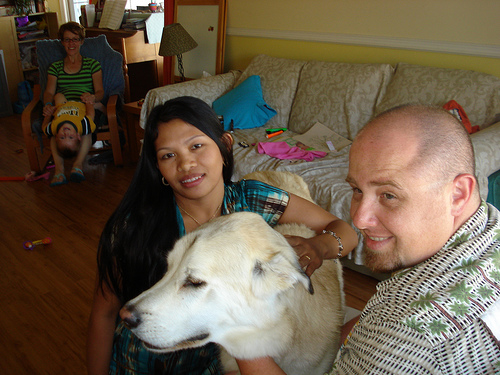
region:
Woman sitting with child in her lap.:
[37, 12, 103, 189]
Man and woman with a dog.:
[80, 95, 490, 367]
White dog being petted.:
[118, 165, 346, 371]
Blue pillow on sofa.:
[210, 75, 280, 135]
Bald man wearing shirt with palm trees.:
[335, 106, 496, 372]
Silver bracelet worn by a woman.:
[308, 220, 348, 260]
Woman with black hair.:
[81, 95, 361, 367]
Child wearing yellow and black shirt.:
[42, 90, 95, 165]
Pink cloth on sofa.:
[255, 131, 325, 162]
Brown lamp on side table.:
[154, 20, 201, 83]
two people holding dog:
[141, 107, 466, 372]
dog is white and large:
[167, 205, 341, 373]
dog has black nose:
[115, 303, 170, 335]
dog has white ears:
[174, 198, 341, 320]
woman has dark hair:
[138, 84, 209, 278]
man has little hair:
[380, 89, 495, 216]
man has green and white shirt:
[362, 219, 497, 374]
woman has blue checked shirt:
[90, 186, 278, 364]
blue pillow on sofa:
[196, 80, 306, 129]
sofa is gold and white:
[247, 62, 495, 225]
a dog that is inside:
[52, 103, 486, 371]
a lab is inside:
[112, 83, 482, 372]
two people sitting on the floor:
[83, 86, 492, 348]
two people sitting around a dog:
[85, 63, 499, 316]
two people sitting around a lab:
[108, 65, 497, 345]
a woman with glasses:
[32, 16, 146, 111]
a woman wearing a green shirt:
[21, 12, 111, 107]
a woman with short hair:
[22, 16, 126, 101]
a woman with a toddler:
[24, 39, 114, 153]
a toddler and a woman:
[14, 11, 166, 148]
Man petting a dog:
[231, 103, 499, 372]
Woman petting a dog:
[84, 94, 359, 373]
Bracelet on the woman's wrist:
[317, 222, 345, 256]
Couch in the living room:
[138, 52, 498, 279]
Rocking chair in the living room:
[19, 29, 126, 177]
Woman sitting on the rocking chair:
[43, 20, 106, 185]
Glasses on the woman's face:
[61, 34, 79, 45]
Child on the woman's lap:
[39, 91, 96, 158]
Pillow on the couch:
[211, 74, 276, 137]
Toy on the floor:
[21, 234, 54, 249]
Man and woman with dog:
[89, 93, 498, 367]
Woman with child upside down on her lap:
[36, 18, 106, 188]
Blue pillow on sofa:
[208, 72, 272, 132]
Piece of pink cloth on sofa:
[254, 134, 332, 163]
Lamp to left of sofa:
[156, 18, 196, 84]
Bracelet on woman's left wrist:
[317, 225, 350, 261]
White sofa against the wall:
[142, 50, 498, 278]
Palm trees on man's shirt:
[404, 236, 498, 341]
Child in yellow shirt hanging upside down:
[45, 96, 100, 183]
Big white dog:
[114, 141, 347, 372]